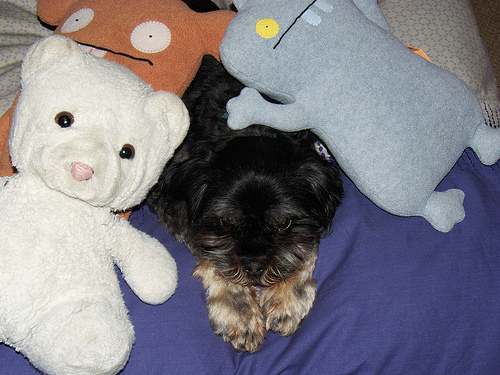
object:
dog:
[140, 0, 346, 354]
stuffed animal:
[0, 32, 194, 375]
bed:
[0, 0, 500, 375]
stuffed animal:
[1, 0, 242, 224]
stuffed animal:
[221, 0, 498, 234]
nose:
[70, 161, 94, 182]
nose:
[243, 261, 265, 277]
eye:
[254, 17, 281, 40]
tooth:
[313, 0, 336, 13]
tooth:
[299, 8, 324, 27]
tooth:
[76, 41, 92, 54]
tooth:
[90, 47, 108, 59]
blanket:
[0, 145, 500, 374]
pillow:
[0, 0, 56, 121]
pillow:
[376, 0, 500, 130]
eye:
[276, 215, 293, 229]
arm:
[107, 216, 179, 304]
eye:
[129, 19, 173, 56]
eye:
[58, 7, 97, 34]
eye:
[53, 111, 75, 129]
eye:
[118, 143, 135, 161]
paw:
[258, 281, 319, 338]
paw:
[205, 290, 269, 355]